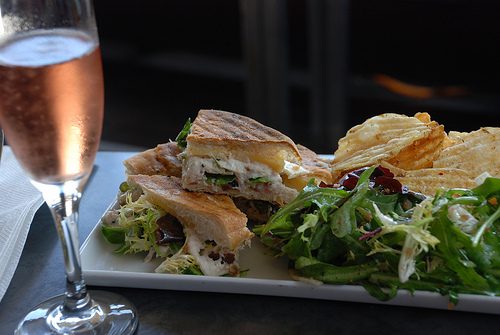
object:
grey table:
[1, 150, 499, 334]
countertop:
[0, 150, 499, 333]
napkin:
[0, 145, 46, 301]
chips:
[328, 112, 433, 172]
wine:
[0, 27, 105, 184]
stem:
[33, 184, 92, 310]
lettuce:
[258, 166, 378, 238]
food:
[180, 109, 311, 203]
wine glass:
[0, 0, 138, 335]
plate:
[78, 155, 499, 314]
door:
[94, 0, 265, 153]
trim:
[324, 0, 349, 147]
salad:
[250, 165, 498, 304]